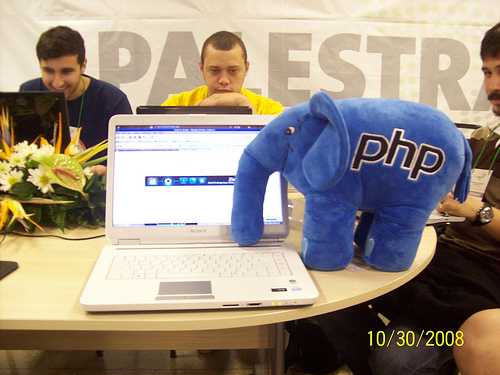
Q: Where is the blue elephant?
A: Near the laptop.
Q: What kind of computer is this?
A: Laptop.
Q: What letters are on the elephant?
A: PHP.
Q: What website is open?
A: Facebook.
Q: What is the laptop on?
A: A table.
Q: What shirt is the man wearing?
A: Yellow.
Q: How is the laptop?
A: It is turned on.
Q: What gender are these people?
A: They are men.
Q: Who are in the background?
A: The men.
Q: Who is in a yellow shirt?
A: The Man behin laptop.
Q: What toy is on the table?
A: A stuffed animal.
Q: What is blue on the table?
A: The animal is blue.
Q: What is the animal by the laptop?
A: An elephant.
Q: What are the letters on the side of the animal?
A: Php.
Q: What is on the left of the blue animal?
A: An open lap top.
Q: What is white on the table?
A: The lap top.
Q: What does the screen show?
A: The screen is on.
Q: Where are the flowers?
A: On the left side of the table.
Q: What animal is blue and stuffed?
A: Elephant.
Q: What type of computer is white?
A: Laptop.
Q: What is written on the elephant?
A: PHP.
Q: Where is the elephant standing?
A: On the table.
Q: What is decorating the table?
A: Flowers.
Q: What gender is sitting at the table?
A: Male.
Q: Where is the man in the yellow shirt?
A: Behind the elephant.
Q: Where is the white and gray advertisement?
A: On the wall.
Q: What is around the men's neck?
A: ID necklaces.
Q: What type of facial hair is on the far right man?
A: Mustache.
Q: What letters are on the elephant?
A: Php.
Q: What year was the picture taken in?
A: 2008.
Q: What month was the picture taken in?
A: October.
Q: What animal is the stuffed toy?
A: Elephant.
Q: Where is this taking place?
A: At a conference table at an event.